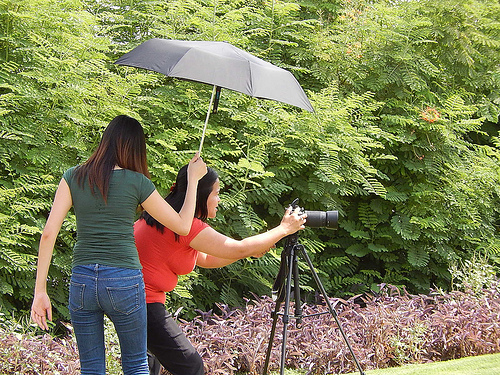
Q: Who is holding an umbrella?
A: The woman.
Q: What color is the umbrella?
A: Black.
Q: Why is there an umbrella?
A: For shade.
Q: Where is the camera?
A: On a tripod.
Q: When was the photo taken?
A: Daytime.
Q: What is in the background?
A: Trees.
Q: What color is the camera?
A: Black.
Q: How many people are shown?
A: Two.